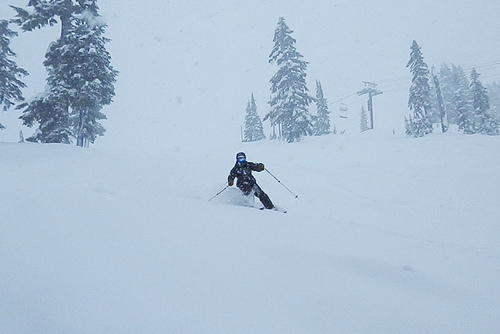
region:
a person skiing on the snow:
[112, 90, 471, 305]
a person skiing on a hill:
[157, 93, 410, 325]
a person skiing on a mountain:
[182, 153, 381, 283]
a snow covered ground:
[49, 143, 433, 329]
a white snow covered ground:
[78, 145, 454, 332]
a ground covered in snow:
[57, 153, 358, 318]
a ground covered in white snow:
[101, 150, 371, 311]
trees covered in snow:
[236, 16, 364, 172]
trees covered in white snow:
[247, 16, 394, 211]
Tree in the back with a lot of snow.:
[231, 85, 262, 146]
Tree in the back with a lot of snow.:
[203, 241, 240, 268]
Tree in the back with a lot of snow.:
[405, 115, 435, 135]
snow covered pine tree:
[265, 13, 315, 143]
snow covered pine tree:
[245, 89, 263, 139]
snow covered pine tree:
[309, 75, 332, 135]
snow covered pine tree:
[403, 38, 437, 135]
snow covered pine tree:
[469, 67, 496, 132]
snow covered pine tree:
[451, 83, 474, 133]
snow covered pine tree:
[358, 104, 370, 131]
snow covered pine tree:
[76, 3, 118, 143]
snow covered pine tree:
[13, 3, 100, 146]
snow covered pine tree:
[438, 60, 457, 118]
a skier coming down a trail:
[207, 132, 299, 244]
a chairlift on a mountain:
[323, 73, 430, 130]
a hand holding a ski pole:
[257, 158, 303, 201]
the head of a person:
[234, 148, 248, 166]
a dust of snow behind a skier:
[198, 171, 252, 209]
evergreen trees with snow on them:
[35, 23, 108, 147]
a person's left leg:
[259, 185, 271, 204]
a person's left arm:
[249, 158, 259, 168]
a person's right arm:
[225, 163, 237, 178]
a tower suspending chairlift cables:
[357, 81, 384, 129]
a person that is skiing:
[112, 109, 437, 281]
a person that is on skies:
[169, 134, 399, 319]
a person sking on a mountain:
[211, 129, 329, 256]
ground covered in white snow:
[74, 156, 363, 316]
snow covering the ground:
[87, 111, 479, 326]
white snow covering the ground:
[64, 126, 494, 319]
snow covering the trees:
[219, 16, 376, 145]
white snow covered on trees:
[232, 26, 409, 175]